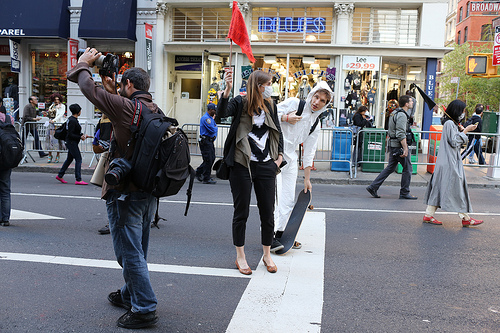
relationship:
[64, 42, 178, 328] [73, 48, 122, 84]
man holding camera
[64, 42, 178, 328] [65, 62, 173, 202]
man wearing shirt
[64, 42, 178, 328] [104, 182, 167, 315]
man wearing jeans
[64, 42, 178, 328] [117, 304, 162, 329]
man wearing shoes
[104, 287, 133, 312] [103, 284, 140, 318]
man wearing shoes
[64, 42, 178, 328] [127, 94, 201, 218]
man wearing backpack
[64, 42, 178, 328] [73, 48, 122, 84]
man with camera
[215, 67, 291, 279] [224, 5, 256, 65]
lady holding flag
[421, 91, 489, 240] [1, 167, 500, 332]
people in street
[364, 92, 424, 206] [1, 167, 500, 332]
people in street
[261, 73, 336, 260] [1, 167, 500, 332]
people in street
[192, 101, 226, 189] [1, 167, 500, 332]
people in street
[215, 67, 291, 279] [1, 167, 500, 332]
lady in street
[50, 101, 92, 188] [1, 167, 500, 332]
people in street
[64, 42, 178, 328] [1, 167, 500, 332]
man in street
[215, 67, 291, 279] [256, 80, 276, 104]
lady wearing mask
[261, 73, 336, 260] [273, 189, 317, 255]
people holding skateboard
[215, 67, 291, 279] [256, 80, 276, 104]
lady in mask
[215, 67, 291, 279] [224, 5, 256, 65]
lady holds flag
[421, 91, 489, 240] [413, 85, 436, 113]
people holds flag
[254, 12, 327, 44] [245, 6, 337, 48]
sign in window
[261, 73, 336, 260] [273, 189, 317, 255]
people holds skateboard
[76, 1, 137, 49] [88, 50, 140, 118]
awning over window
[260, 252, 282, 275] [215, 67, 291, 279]
shoes of lady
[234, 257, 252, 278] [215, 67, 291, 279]
shoes of lady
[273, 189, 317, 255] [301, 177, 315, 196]
skateboard in hand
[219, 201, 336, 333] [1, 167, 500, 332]
line on street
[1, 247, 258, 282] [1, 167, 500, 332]
line on street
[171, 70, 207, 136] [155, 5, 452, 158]
door of building